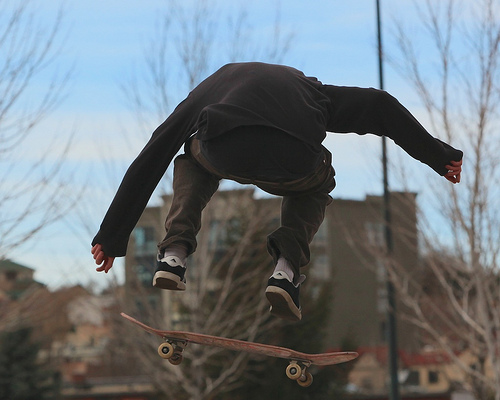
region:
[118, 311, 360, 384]
A dirty skateboard.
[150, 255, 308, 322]
White and black shoes.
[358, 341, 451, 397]
A building with a red roof.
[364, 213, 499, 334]
No leaves on the branches.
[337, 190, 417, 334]
Part of a building in the background.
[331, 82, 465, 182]
The skateboarder's right arm.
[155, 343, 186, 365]
Two beige wheels.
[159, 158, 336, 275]
Brown pants and white socks.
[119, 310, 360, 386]
The skateboard is in the air.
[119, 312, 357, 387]
The skateboard is a dingy red color.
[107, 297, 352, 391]
the skateboard is in the air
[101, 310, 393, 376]
the skateboard is red in color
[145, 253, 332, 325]
the shoes are black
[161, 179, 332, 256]
the pants are brown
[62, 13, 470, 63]
the sky is blue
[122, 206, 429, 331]
the building is brown in color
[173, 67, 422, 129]
the top is black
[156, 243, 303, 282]
the socks are white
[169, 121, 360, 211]
the pants are sagging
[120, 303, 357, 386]
a red skateboard in the air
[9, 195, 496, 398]
buildings in the background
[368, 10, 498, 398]
a tall leafless tree on the side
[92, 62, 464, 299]
a man crouched above the skateboard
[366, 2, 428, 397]
a tall pole next to the tree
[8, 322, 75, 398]
a shorter tree in the corner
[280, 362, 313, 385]
some wheels on the skateboard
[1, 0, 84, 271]
another tall leafless tree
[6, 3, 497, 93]
the bright blue sky with a few clouds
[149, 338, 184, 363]
the other wheels of the skateboard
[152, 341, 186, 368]
pair of yellow wheels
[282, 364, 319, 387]
pair of yellow wheels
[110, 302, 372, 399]
red skateboard in the air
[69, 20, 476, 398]
person jumping in the air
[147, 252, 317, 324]
pair of black and white sneakers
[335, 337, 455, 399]
out of focus tan building with a red roof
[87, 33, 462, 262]
black long sleeved shirt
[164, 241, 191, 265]
white sock underneath dark pants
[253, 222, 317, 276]
dark brown pants cuff over a white sock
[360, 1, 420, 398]
out of focus black metal pole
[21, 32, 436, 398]
the man is on the air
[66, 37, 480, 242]
person is wearing long sleeves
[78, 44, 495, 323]
the long sleeve is black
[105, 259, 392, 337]
the man is wearing shoes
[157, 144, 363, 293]
the pants are brown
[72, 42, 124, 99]
the sky is blue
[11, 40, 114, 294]
the trees are bare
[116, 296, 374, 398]
the skateboard is brown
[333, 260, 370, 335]
the wall is gray